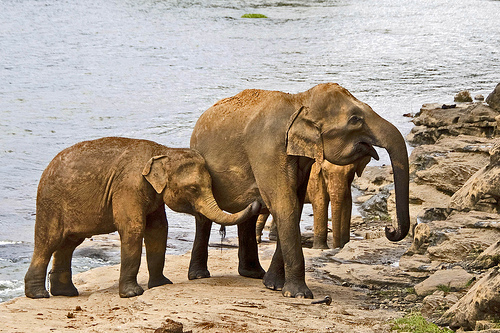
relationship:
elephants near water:
[23, 83, 420, 299] [1, 5, 500, 213]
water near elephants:
[1, 5, 500, 213] [23, 83, 420, 299]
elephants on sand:
[23, 83, 420, 299] [16, 234, 422, 331]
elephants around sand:
[23, 83, 420, 299] [16, 234, 422, 331]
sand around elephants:
[16, 234, 422, 331] [23, 83, 420, 299]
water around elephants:
[1, 5, 500, 213] [23, 83, 420, 299]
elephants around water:
[23, 83, 420, 299] [1, 5, 500, 213]